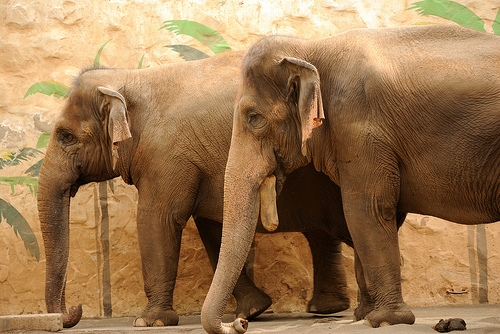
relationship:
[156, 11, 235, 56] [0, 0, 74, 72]
leaves painted on brown wall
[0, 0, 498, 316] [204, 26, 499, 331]
walls near elephant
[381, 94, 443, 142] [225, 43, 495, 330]
skin of elephant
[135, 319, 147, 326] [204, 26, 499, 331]
nail of elephant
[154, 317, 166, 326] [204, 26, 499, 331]
nail of elephant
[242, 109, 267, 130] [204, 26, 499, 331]
eye of elephant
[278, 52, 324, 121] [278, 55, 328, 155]
border of ear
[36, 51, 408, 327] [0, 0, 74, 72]
elephant in front of brown wall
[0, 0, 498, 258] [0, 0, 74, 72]
leaves painted on brown wall